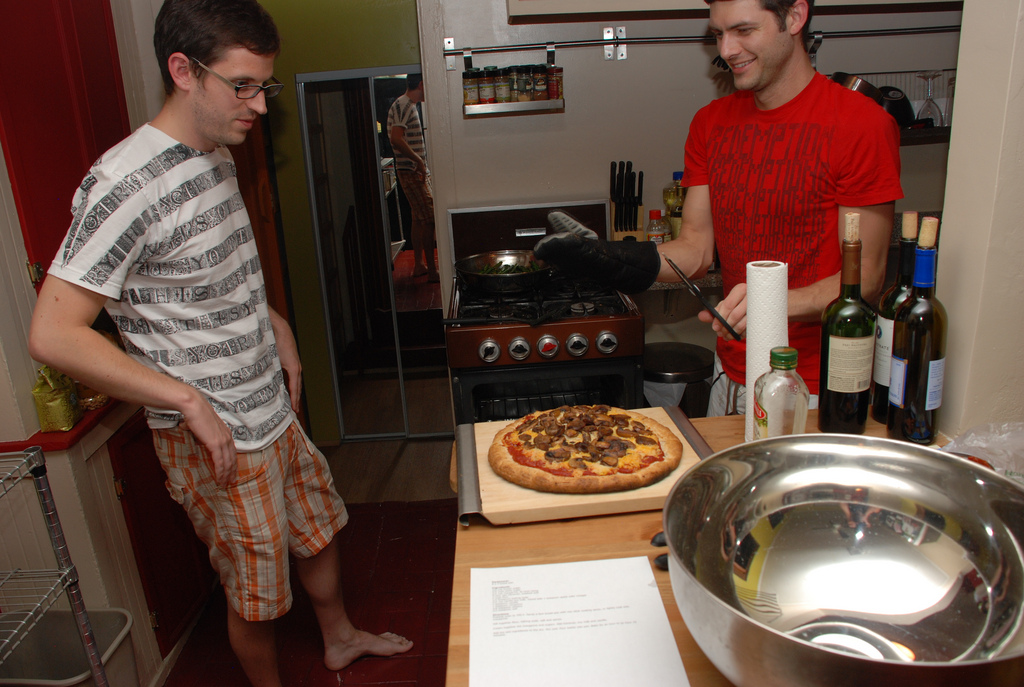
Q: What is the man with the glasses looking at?
A: A pizza.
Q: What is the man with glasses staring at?
A: A pizza on the counter that just came out of the oven.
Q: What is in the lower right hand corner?
A: A large empty silver mixing bowl.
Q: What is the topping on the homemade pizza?
A: Fresh mushrooms.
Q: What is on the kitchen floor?
A: Tiles.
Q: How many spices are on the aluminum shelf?
A: Six spices.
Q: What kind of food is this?
A: The food is pizza.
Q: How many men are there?
A: Two.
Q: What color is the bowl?
A: It is silver.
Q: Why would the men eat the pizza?
A: They are hungry.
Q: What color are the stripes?
A: Gray and white.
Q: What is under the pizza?
A: A cutting board.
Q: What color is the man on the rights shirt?
A: It is red.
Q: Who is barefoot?
A: The man on the left.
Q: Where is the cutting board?
A: It is on the table.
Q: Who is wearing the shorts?
A: A boy.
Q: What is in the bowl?
A: Empty.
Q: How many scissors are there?
A: 1.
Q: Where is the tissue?
A: On the table.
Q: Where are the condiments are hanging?
A: Wall.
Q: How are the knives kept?
A: In the stand.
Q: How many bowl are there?
A: 1.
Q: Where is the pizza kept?
A: In the wooden plate.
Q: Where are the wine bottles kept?
A: Table.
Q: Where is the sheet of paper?
A: Counter.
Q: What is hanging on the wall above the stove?
A: Spice rack.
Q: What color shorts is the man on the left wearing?
A: Orange and white.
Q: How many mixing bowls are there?
A: One.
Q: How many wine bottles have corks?
A: Three.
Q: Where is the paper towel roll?
A: By wine bottles.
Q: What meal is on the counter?
A: Pizza.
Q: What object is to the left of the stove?
A: Mirror.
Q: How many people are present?
A: Two.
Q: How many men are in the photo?
A: 2.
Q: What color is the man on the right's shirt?
A: Red.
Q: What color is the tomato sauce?
A: Red.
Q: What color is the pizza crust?
A: Brown.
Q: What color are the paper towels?
A: White.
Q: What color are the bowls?
A: Gray.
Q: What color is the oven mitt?
A: Black.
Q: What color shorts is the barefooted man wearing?
A: Orange.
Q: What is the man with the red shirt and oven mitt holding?
A: Scissors.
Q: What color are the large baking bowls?
A: Silver.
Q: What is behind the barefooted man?
A: Mirror.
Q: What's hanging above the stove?
A: Spice rack.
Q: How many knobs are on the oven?
A: 5.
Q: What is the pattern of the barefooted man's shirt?
A: Grey and white stripes.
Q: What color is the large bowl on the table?
A: Silver.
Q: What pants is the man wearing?
A: Orange plaid shorts.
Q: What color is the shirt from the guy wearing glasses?
A: White and black.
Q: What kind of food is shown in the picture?
A: Pizza.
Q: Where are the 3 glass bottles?
A: Next to the wall on the counter.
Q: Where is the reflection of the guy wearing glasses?
A: On the mirror on the yellow wall.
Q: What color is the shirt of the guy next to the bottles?
A: Red.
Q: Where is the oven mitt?
A: On the man's hand.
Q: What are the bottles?
A: A drinking beverage.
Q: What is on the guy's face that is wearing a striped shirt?
A: Glasses.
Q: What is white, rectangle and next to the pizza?
A: A paper.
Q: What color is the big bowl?
A: Silver.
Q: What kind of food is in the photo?
A: A pizza.